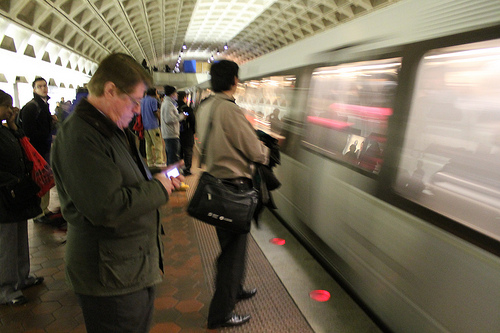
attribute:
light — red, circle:
[307, 289, 333, 303]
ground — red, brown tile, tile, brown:
[0, 138, 386, 329]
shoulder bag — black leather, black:
[186, 100, 257, 235]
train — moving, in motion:
[176, 1, 498, 329]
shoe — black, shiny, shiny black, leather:
[210, 312, 254, 327]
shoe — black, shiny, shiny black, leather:
[236, 287, 259, 301]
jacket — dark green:
[48, 99, 169, 297]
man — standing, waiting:
[140, 87, 167, 172]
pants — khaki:
[142, 127, 168, 166]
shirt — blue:
[140, 95, 159, 128]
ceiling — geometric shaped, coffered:
[1, 0, 395, 71]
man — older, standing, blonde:
[51, 53, 185, 333]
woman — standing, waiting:
[0, 89, 45, 305]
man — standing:
[194, 60, 268, 328]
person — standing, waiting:
[18, 79, 57, 226]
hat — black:
[163, 83, 177, 98]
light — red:
[268, 234, 287, 246]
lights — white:
[206, 45, 230, 65]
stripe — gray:
[249, 206, 381, 333]